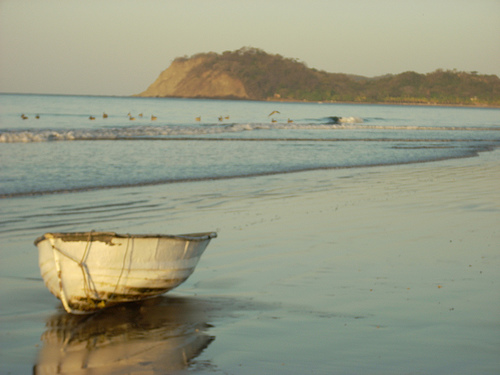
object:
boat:
[31, 222, 220, 315]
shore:
[0, 149, 498, 374]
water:
[1, 91, 499, 195]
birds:
[283, 115, 298, 129]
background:
[1, 1, 498, 199]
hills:
[137, 48, 499, 104]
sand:
[0, 155, 496, 374]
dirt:
[75, 295, 89, 305]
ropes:
[74, 233, 97, 300]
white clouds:
[21, 12, 138, 49]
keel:
[63, 298, 157, 310]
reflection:
[27, 301, 216, 375]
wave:
[1, 122, 499, 140]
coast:
[3, 148, 499, 197]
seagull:
[267, 109, 282, 119]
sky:
[2, 0, 499, 50]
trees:
[437, 66, 453, 79]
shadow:
[45, 298, 272, 321]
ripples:
[19, 198, 149, 211]